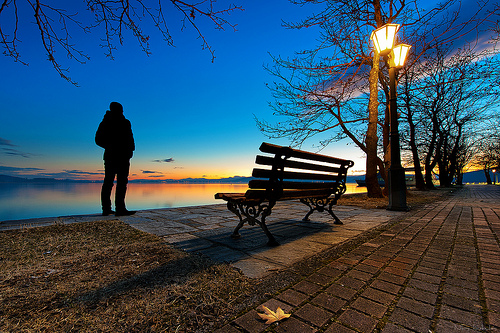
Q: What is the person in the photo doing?
A: Standing.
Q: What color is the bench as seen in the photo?
A: Black.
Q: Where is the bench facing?
A: The water.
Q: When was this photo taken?
A: At sunset.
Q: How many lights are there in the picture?
A: Two.